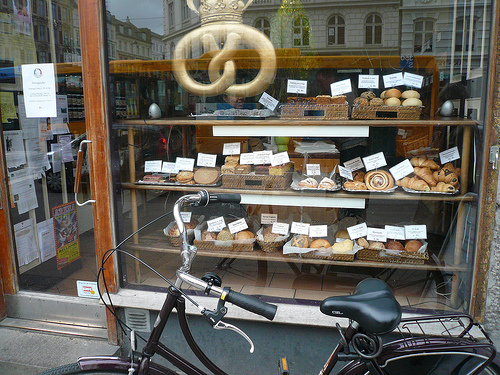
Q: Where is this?
A: This is at the bakery.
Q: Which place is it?
A: It is a bakery.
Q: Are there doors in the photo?
A: Yes, there is a door.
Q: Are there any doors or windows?
A: Yes, there is a door.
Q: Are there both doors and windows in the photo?
A: Yes, there are both a door and a window.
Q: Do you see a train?
A: No, there are no trains.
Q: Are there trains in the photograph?
A: No, there are no trains.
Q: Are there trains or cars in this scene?
A: No, there are no trains or cars.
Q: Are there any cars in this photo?
A: No, there are no cars.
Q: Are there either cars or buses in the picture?
A: No, there are no cars or buses.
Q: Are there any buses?
A: No, there are no buses.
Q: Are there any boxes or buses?
A: No, there are no buses or boxes.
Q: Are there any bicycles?
A: Yes, there is a bicycle.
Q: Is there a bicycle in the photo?
A: Yes, there is a bicycle.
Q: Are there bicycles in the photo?
A: Yes, there is a bicycle.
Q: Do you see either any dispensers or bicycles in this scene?
A: Yes, there is a bicycle.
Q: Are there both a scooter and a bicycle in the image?
A: No, there is a bicycle but no scooters.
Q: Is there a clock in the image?
A: No, there are no clocks.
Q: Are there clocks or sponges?
A: No, there are no clocks or sponges.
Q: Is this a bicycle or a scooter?
A: This is a bicycle.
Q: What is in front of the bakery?
A: The bicycle is in front of the bakery.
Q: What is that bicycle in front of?
A: The bicycle is in front of the bakery.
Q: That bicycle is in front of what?
A: The bicycle is in front of the bakery.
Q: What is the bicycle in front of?
A: The bicycle is in front of the bakery.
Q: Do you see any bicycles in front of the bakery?
A: Yes, there is a bicycle in front of the bakery.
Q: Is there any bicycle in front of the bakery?
A: Yes, there is a bicycle in front of the bakery.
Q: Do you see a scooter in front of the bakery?
A: No, there is a bicycle in front of the bakery.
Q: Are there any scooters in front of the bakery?
A: No, there is a bicycle in front of the bakery.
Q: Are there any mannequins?
A: No, there are no mannequins.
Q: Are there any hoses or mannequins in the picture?
A: No, there are no mannequins or hoses.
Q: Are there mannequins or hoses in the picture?
A: No, there are no mannequins or hoses.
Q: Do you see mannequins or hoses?
A: No, there are no mannequins or hoses.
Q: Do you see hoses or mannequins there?
A: No, there are no mannequins or hoses.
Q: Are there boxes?
A: No, there are no boxes.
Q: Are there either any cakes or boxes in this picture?
A: No, there are no boxes or cakes.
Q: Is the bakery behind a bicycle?
A: Yes, the bakery is behind a bicycle.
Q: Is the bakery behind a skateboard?
A: No, the bakery is behind a bicycle.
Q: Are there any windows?
A: Yes, there is a window.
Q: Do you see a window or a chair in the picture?
A: Yes, there is a window.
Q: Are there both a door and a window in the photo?
A: Yes, there are both a window and a door.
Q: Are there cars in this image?
A: No, there are no cars.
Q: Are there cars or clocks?
A: No, there are no cars or clocks.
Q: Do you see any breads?
A: Yes, there is a bread.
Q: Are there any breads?
A: Yes, there is a bread.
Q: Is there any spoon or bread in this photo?
A: Yes, there is a bread.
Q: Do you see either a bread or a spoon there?
A: Yes, there is a bread.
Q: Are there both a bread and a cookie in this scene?
A: No, there is a bread but no cookies.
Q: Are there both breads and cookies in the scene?
A: No, there is a bread but no cookies.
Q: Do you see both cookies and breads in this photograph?
A: No, there is a bread but no cookies.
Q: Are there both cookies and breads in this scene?
A: No, there is a bread but no cookies.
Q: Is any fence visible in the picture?
A: No, there are no fences.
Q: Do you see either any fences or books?
A: No, there are no fences or books.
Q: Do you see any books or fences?
A: No, there are no fences or books.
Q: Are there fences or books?
A: No, there are no fences or books.